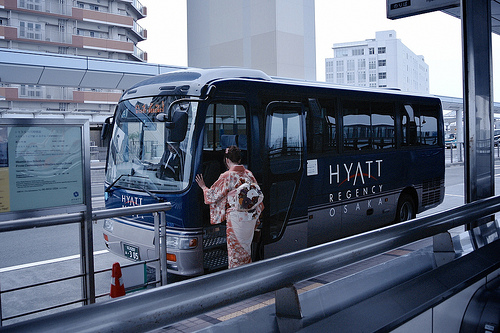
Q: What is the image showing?
A: It is showing a road.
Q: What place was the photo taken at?
A: It was taken at the road.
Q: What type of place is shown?
A: It is a road.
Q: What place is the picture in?
A: It is at the road.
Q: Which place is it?
A: It is a road.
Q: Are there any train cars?
A: No, there are no train cars.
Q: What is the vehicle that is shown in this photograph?
A: The vehicle is a van.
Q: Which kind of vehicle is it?
A: The vehicle is a van.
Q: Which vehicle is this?
A: This is a van.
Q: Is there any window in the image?
A: Yes, there is a window.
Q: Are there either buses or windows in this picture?
A: Yes, there is a window.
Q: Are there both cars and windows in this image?
A: No, there is a window but no cars.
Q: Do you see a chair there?
A: No, there are no chairs.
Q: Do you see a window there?
A: Yes, there is a window.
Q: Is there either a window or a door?
A: Yes, there is a window.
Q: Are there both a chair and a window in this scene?
A: No, there is a window but no chairs.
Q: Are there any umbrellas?
A: No, there are no umbrellas.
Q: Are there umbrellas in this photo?
A: No, there are no umbrellas.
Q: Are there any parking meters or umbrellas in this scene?
A: No, there are no umbrellas or parking meters.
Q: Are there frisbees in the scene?
A: No, there are no frisbees.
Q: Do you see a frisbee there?
A: No, there are no frisbees.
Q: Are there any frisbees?
A: No, there are no frisbees.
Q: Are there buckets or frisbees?
A: No, there are no frisbees or buckets.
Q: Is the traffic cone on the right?
A: No, the traffic cone is on the left of the image.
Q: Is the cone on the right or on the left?
A: The cone is on the left of the image.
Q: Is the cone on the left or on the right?
A: The cone is on the left of the image.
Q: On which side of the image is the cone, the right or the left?
A: The cone is on the left of the image.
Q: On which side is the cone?
A: The cone is on the left of the image.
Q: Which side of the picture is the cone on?
A: The cone is on the left of the image.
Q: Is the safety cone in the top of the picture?
A: No, the safety cone is in the bottom of the image.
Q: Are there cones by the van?
A: Yes, there is a cone by the van.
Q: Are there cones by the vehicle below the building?
A: Yes, there is a cone by the van.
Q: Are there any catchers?
A: No, there are no catchers.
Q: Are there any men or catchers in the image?
A: No, there are no catchers or men.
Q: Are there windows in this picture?
A: Yes, there is a window.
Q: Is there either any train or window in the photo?
A: Yes, there is a window.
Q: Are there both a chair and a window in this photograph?
A: No, there is a window but no chairs.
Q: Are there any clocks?
A: No, there are no clocks.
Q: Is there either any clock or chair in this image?
A: No, there are no clocks or chairs.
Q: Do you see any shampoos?
A: No, there are no shampoos.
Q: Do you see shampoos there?
A: No, there are no shampoos.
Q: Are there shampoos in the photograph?
A: No, there are no shampoos.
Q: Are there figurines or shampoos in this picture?
A: No, there are no shampoos or figurines.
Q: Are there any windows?
A: Yes, there is a window.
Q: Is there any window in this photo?
A: Yes, there is a window.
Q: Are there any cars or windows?
A: Yes, there is a window.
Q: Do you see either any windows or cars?
A: Yes, there is a window.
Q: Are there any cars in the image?
A: No, there are no cars.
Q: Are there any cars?
A: No, there are no cars.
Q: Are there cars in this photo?
A: No, there are no cars.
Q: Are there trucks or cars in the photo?
A: No, there are no cars or trucks.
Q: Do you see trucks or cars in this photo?
A: No, there are no cars or trucks.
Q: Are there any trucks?
A: No, there are no trucks.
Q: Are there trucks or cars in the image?
A: No, there are no trucks or cars.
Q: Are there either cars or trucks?
A: No, there are no trucks or cars.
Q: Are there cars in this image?
A: No, there are no cars.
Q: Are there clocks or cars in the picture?
A: No, there are no cars or clocks.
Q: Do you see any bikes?
A: No, there are no bikes.